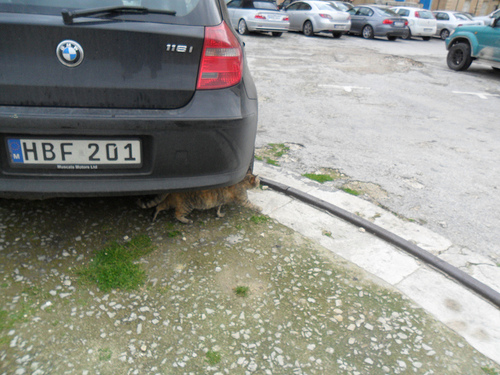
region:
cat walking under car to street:
[112, 91, 422, 241]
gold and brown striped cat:
[142, 169, 286, 234]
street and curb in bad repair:
[265, 116, 450, 246]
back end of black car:
[35, 22, 252, 178]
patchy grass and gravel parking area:
[37, 243, 404, 357]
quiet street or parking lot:
[194, 0, 469, 183]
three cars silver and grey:
[237, 1, 414, 44]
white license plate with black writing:
[6, 129, 147, 174]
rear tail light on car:
[177, 16, 247, 98]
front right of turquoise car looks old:
[441, 9, 486, 89]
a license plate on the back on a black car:
[3, 129, 153, 182]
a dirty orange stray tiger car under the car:
[136, 171, 282, 226]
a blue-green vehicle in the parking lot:
[444, 7, 499, 74]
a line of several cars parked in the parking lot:
[225, 0, 455, 42]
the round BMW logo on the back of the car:
[50, 35, 87, 70]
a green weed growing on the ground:
[63, 242, 161, 299]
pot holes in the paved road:
[270, 137, 427, 214]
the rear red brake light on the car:
[193, 17, 250, 104]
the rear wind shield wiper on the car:
[49, 0, 184, 28]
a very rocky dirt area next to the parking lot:
[174, 303, 406, 368]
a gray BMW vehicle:
[0, 0, 261, 200]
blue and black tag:
[3, 134, 145, 170]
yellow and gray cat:
[138, 171, 261, 228]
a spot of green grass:
[76, 224, 159, 296]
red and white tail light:
[194, 18, 244, 94]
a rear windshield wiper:
[59, 6, 180, 26]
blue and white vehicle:
[446, 9, 498, 71]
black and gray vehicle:
[223, 0, 293, 38]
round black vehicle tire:
[446, 40, 472, 72]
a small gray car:
[339, 4, 410, 41]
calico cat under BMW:
[48, 3, 325, 250]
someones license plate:
[0, 110, 184, 174]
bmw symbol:
[42, 35, 92, 87]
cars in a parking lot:
[222, 0, 496, 105]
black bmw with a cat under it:
[0, 3, 312, 238]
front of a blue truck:
[432, 2, 497, 77]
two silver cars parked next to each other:
[223, 0, 361, 45]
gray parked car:
[342, 0, 412, 49]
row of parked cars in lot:
[226, 1, 497, 43]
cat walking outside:
[117, 156, 290, 248]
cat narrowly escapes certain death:
[126, 163, 291, 228]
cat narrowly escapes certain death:
[139, 152, 216, 205]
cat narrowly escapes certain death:
[106, 142, 306, 261]